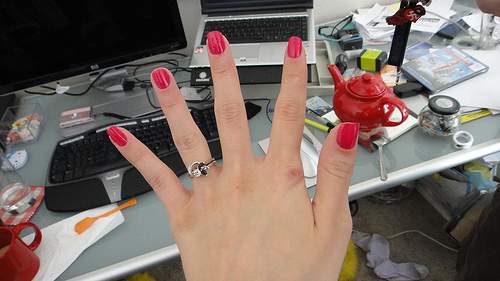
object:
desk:
[0, 1, 497, 281]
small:
[376, 146, 390, 178]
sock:
[350, 232, 431, 281]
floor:
[347, 185, 469, 276]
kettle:
[327, 64, 410, 131]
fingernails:
[104, 125, 127, 147]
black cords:
[22, 59, 212, 108]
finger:
[312, 121, 360, 228]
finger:
[265, 36, 307, 161]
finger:
[108, 124, 191, 208]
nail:
[336, 122, 360, 150]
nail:
[287, 37, 302, 59]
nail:
[207, 31, 225, 55]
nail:
[152, 69, 172, 90]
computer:
[187, 1, 317, 68]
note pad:
[0, 148, 29, 170]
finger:
[149, 67, 217, 190]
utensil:
[73, 199, 137, 235]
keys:
[200, 15, 309, 46]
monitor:
[0, 0, 185, 87]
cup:
[0, 222, 42, 281]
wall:
[305, 0, 356, 18]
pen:
[305, 117, 334, 133]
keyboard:
[42, 106, 222, 213]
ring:
[187, 157, 218, 179]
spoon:
[370, 134, 388, 182]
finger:
[205, 31, 250, 167]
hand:
[106, 31, 361, 281]